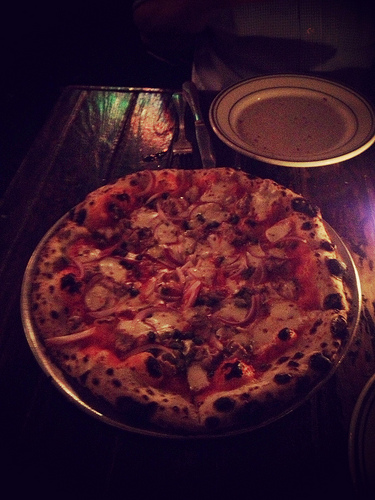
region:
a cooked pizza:
[16, 90, 335, 492]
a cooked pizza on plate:
[37, 163, 364, 435]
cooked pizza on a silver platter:
[27, 176, 372, 457]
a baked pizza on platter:
[56, 175, 302, 425]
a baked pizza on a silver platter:
[27, 179, 362, 449]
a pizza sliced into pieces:
[36, 178, 369, 446]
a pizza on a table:
[30, 166, 372, 470]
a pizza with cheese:
[42, 160, 372, 438]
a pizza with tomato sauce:
[49, 181, 372, 447]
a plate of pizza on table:
[34, 152, 348, 495]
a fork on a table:
[162, 83, 193, 168]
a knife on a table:
[181, 82, 218, 173]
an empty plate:
[211, 73, 373, 169]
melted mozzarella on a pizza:
[155, 221, 195, 261]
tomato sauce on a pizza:
[290, 246, 317, 306]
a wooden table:
[40, 73, 148, 167]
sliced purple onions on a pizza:
[219, 260, 273, 335]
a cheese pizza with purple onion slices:
[61, 180, 326, 416]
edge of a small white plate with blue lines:
[349, 372, 373, 493]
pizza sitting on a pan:
[17, 159, 356, 435]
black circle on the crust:
[214, 396, 235, 412]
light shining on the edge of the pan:
[57, 379, 96, 415]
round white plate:
[194, 67, 374, 176]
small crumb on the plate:
[322, 95, 329, 103]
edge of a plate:
[344, 388, 374, 477]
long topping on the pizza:
[215, 295, 266, 329]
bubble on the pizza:
[211, 357, 254, 389]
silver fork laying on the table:
[169, 89, 196, 160]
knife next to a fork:
[155, 83, 226, 169]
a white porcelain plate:
[206, 71, 374, 172]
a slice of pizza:
[178, 273, 353, 436]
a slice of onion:
[214, 288, 266, 327]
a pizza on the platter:
[25, 163, 355, 438]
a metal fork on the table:
[165, 88, 194, 163]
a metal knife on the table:
[180, 72, 222, 168]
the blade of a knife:
[190, 117, 221, 169]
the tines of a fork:
[169, 132, 196, 160]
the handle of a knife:
[181, 78, 204, 124]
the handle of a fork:
[169, 88, 190, 134]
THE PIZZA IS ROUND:
[12, 168, 364, 440]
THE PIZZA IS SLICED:
[28, 162, 348, 431]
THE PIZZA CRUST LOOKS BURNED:
[30, 163, 352, 439]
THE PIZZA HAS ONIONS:
[85, 199, 275, 362]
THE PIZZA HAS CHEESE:
[30, 162, 359, 440]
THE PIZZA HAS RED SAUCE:
[20, 165, 359, 443]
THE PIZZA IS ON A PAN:
[22, 166, 363, 448]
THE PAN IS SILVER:
[20, 193, 362, 448]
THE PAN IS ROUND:
[11, 179, 373, 440]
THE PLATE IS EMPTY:
[205, 70, 373, 177]